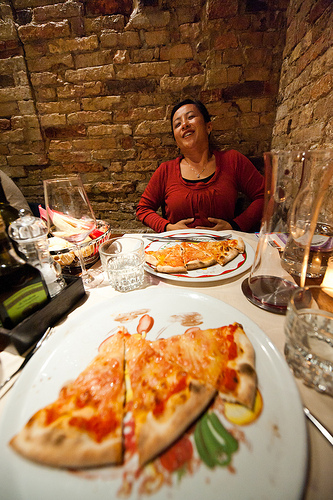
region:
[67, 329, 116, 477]
slice of pizza with toppings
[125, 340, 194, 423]
slice of pizza with toppings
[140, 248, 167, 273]
slice of pizza with toppings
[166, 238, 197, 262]
slice of pizza with toppings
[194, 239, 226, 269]
slice of pizza with toppings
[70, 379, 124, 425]
slice of pizza with toppings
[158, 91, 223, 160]
head of the lady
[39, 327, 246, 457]
pizza on the plate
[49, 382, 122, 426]
sauce on the pizza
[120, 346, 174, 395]
cheese on the pizza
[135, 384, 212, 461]
crust of the pizza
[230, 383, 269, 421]
corner of the crust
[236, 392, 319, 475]
plate under the pizza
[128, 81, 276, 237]
woman wearing a red shirt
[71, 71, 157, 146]
bricks behind the lady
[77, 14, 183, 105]
lines on the wall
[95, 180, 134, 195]
a brick is on the wall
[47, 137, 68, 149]
a brick is on the wall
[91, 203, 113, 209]
a brick is on the wall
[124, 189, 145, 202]
a brick is on the wall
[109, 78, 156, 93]
a brick is on the wall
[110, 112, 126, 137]
a brick is on the wall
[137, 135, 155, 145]
a brick is on the wall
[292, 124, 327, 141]
a brick is on the wall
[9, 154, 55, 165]
a brick is on the wall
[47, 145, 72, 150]
a brick is on the wall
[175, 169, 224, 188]
black shirt keeping over orange shirt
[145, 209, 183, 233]
sleeve of red shirt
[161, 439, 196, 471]
slice of red pepperoni on plate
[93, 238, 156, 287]
small clear crystal glass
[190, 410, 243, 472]
green leaf on plate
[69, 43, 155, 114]
brown stone on the wall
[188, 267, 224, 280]
red color on plate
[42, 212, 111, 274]
basket on the table top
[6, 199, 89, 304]
salt shaker in black basket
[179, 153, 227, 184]
silver necklace around woman's neck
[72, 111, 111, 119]
a brick on wall of a building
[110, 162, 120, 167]
a brick on wall of a building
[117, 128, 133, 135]
a brick on wall of a building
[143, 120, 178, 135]
a brick on wall of a building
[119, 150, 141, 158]
a brick on wall of a building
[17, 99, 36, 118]
a brick on wall of a building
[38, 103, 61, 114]
a brick on wall of a building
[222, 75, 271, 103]
a brick on wall of a building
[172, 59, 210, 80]
a brick on wall of a building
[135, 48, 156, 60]
a brick on wall of a building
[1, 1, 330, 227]
two walls made of distressed brick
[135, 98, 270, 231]
seated woman with hands on stomach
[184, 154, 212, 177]
jewelry on woman's neck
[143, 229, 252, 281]
plate with five slices of pizza